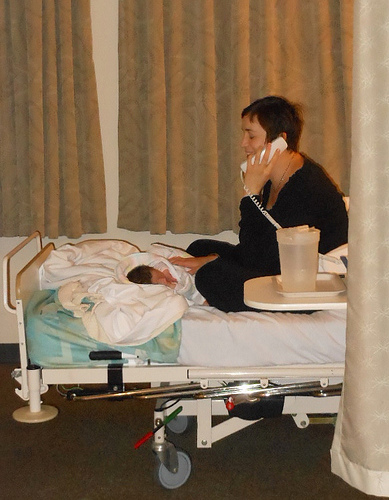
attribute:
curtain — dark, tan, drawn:
[0, 0, 111, 240]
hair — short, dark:
[235, 92, 306, 155]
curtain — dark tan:
[111, 1, 359, 231]